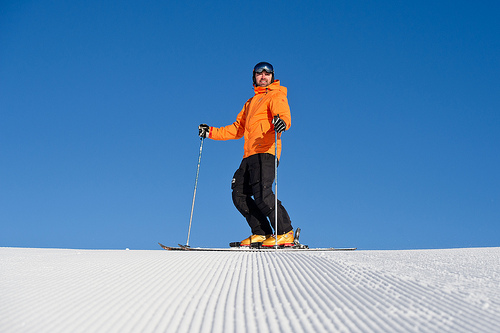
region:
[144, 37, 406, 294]
this person is skiing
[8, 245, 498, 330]
the snow has been raked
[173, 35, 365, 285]
he is wearing bright colors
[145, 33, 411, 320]
he is standing on his skis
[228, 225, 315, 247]
his ski boots are orange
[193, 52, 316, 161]
his jacket is orange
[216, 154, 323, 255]
his pants are black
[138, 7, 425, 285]
he is standing perpendicular to the slope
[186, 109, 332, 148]
his gloves are black and white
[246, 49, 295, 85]
his hat and goggles are black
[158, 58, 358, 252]
A man on snow skis.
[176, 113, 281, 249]
Man holding two ski poles.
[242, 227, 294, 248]
Brown ski shoes.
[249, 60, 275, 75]
A pair of snow goggles on the man's head.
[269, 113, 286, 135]
Black glove on the man's hand.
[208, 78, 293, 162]
The man is wearing an orange ski coat.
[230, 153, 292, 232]
The man is wearing black ski pants.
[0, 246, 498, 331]
white snow on the ground.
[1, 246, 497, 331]
Ridges in the snow.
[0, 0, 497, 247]
Bright blue sky behind the man.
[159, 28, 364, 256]
the man is skiing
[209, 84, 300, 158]
man's jacket is orange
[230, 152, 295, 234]
man's pants are black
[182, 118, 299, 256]
man holding ski poles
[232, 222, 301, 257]
man's shoes are orange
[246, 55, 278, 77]
goggles on man's head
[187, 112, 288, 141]
man's gloves are black and white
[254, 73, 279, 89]
man has a mustache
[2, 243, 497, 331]
lines in the snow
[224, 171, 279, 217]
man's knees slightly bent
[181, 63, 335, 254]
a man skiing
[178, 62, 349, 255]
a man standing on the snow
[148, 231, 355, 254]
the skis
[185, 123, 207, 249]
the ski pole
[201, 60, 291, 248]
a man wearing an orange jacket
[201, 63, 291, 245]
a man wearing black pants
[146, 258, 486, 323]
tracks in the snow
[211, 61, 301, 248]
a man with goggles on his head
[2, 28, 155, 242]
the clear blue sky in the background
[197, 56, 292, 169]
a man wearing black gloves